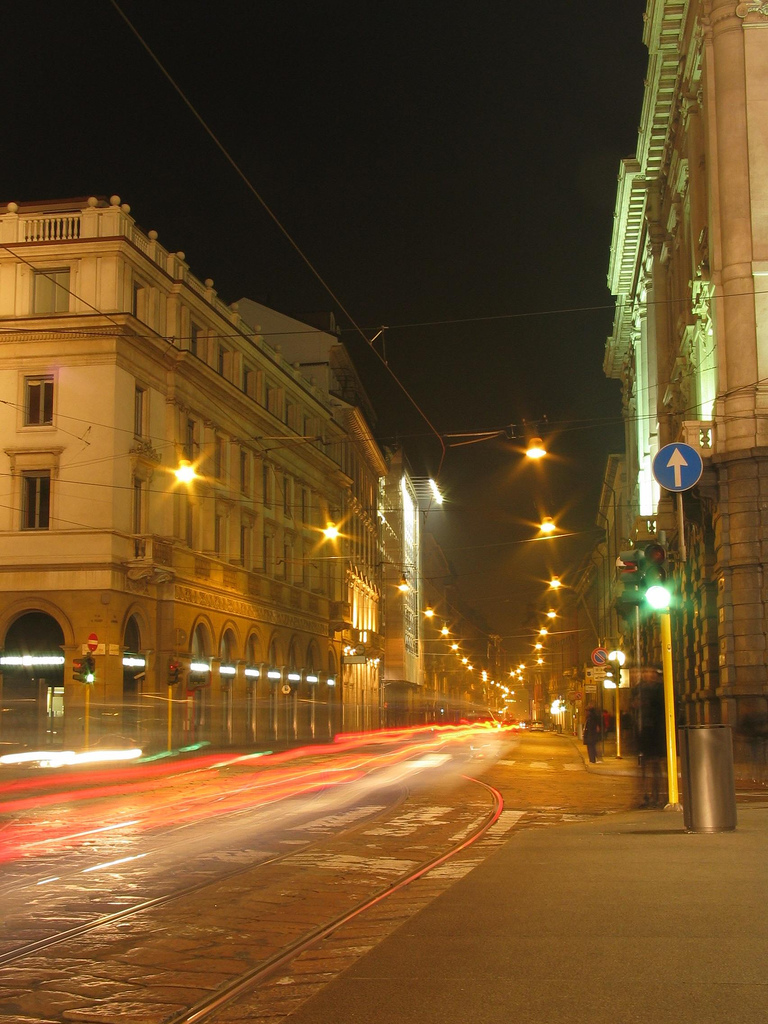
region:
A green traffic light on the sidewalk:
[644, 579, 674, 619]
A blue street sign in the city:
[652, 439, 701, 492]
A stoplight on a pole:
[73, 643, 98, 757]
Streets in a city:
[9, 721, 766, 995]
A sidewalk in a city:
[27, 800, 763, 1021]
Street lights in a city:
[503, 419, 578, 687]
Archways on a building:
[0, 594, 340, 750]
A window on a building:
[17, 468, 57, 534]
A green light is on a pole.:
[640, 583, 679, 813]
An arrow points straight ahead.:
[656, 440, 702, 492]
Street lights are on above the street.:
[168, 440, 552, 698]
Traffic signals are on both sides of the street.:
[68, 532, 695, 810]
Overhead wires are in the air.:
[111, 0, 589, 502]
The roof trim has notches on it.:
[605, 0, 692, 315]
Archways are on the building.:
[0, 604, 348, 742]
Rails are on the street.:
[9, 755, 503, 1019]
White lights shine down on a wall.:
[399, 469, 443, 675]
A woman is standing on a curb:
[580, 701, 608, 773]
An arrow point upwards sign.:
[625, 425, 718, 507]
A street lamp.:
[625, 534, 698, 819]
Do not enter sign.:
[73, 623, 109, 663]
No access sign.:
[579, 635, 619, 676]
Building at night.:
[6, 188, 381, 761]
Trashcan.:
[664, 717, 739, 849]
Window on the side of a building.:
[4, 439, 63, 545]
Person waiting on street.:
[570, 702, 605, 766]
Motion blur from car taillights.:
[2, 660, 543, 893]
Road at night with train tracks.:
[17, 657, 567, 1022]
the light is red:
[2, 825, 37, 867]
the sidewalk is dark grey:
[405, 912, 647, 1015]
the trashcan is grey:
[665, 716, 742, 836]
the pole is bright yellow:
[638, 610, 682, 816]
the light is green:
[646, 580, 676, 618]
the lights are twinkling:
[514, 563, 579, 666]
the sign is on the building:
[172, 576, 310, 635]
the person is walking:
[580, 705, 606, 755]